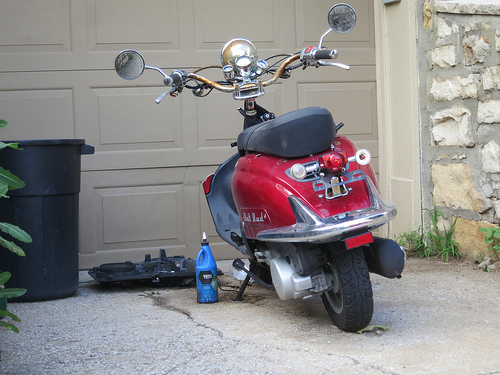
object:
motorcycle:
[114, 2, 407, 332]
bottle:
[195, 232, 219, 303]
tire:
[320, 241, 374, 332]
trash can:
[2, 139, 94, 304]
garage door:
[1, 1, 381, 275]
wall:
[416, 0, 499, 270]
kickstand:
[233, 266, 259, 301]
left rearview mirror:
[114, 49, 145, 80]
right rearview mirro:
[328, 3, 358, 34]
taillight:
[318, 150, 348, 174]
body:
[203, 137, 395, 242]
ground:
[2, 255, 499, 374]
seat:
[237, 106, 338, 157]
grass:
[400, 205, 460, 261]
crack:
[143, 288, 390, 374]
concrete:
[0, 258, 499, 371]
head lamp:
[221, 37, 259, 72]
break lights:
[291, 149, 371, 181]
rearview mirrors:
[114, 3, 357, 81]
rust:
[186, 54, 302, 97]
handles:
[164, 47, 347, 93]